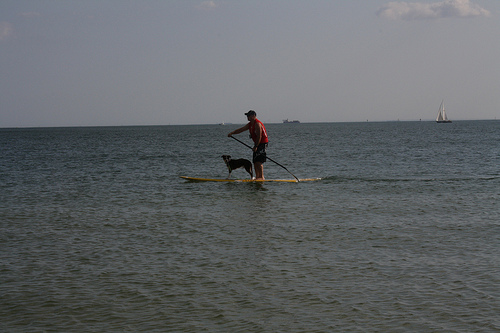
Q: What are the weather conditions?
A: It is cloudy.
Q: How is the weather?
A: It is cloudy.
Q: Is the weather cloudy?
A: Yes, it is cloudy.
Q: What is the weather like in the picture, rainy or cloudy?
A: It is cloudy.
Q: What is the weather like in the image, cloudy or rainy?
A: It is cloudy.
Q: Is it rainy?
A: No, it is cloudy.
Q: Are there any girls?
A: No, there are no girls.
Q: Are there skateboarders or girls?
A: No, there are no girls or skateboarders.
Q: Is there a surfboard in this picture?
A: Yes, there is a surfboard.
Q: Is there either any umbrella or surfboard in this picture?
A: Yes, there is a surfboard.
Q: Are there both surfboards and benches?
A: No, there is a surfboard but no benches.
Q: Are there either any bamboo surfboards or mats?
A: Yes, there is a bamboo surfboard.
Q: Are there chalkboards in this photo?
A: No, there are no chalkboards.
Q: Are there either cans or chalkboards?
A: No, there are no chalkboards or cans.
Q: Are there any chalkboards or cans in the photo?
A: No, there are no chalkboards or cans.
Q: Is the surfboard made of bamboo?
A: Yes, the surfboard is made of bamboo.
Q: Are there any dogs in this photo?
A: Yes, there is a dog.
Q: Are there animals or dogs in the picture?
A: Yes, there is a dog.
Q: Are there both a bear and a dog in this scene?
A: No, there is a dog but no bears.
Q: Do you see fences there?
A: No, there are no fences.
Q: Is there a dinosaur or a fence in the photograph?
A: No, there are no fences or dinosaurs.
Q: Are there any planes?
A: No, there are no planes.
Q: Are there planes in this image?
A: No, there are no planes.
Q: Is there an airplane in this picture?
A: No, there are no airplanes.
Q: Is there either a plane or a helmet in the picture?
A: No, there are no airplanes or helmets.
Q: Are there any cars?
A: No, there are no cars.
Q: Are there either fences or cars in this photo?
A: No, there are no cars or fences.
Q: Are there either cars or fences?
A: No, there are no cars or fences.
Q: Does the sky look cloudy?
A: Yes, the sky is cloudy.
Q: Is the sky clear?
A: No, the sky is cloudy.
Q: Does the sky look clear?
A: No, the sky is cloudy.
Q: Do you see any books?
A: No, there are no books.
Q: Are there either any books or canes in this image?
A: No, there are no books or canes.